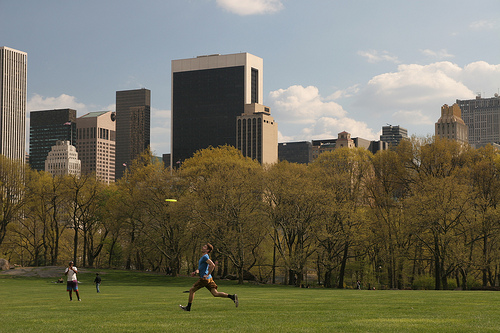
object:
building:
[164, 51, 280, 177]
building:
[76, 110, 115, 192]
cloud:
[0, 0, 499, 119]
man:
[60, 261, 82, 299]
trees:
[0, 132, 500, 289]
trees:
[367, 148, 420, 290]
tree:
[407, 135, 477, 290]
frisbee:
[162, 197, 180, 204]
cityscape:
[0, 1, 500, 183]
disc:
[165, 196, 175, 203]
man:
[182, 242, 242, 313]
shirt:
[197, 254, 213, 279]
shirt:
[63, 267, 79, 282]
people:
[91, 268, 103, 295]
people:
[354, 279, 363, 291]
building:
[433, 101, 468, 160]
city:
[1, 0, 498, 330]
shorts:
[191, 277, 218, 291]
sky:
[1, 0, 499, 159]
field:
[0, 246, 498, 332]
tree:
[450, 142, 498, 288]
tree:
[316, 140, 375, 288]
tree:
[263, 157, 323, 282]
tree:
[169, 170, 271, 283]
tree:
[172, 143, 267, 283]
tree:
[105, 148, 181, 273]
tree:
[65, 165, 114, 268]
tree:
[0, 161, 45, 261]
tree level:
[0, 165, 499, 227]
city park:
[0, 135, 499, 330]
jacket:
[91, 275, 104, 284]